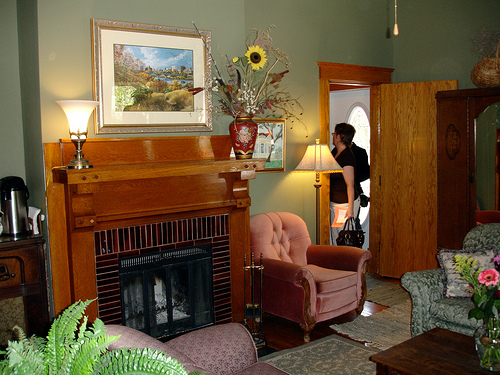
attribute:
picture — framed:
[86, 16, 217, 139]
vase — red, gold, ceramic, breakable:
[225, 111, 262, 159]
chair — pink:
[248, 207, 380, 344]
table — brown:
[361, 323, 475, 375]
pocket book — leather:
[334, 214, 367, 249]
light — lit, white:
[53, 96, 103, 141]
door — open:
[364, 73, 439, 278]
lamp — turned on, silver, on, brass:
[54, 96, 102, 170]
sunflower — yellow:
[240, 43, 272, 74]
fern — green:
[1, 291, 202, 375]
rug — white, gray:
[263, 329, 373, 374]